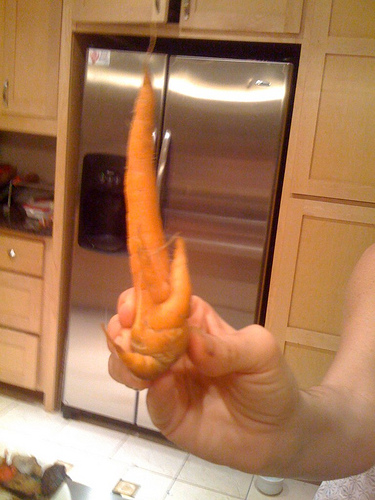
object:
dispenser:
[77, 151, 126, 256]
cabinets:
[0, 0, 64, 121]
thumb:
[186, 323, 281, 381]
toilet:
[51, 40, 296, 438]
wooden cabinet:
[328, 0, 374, 44]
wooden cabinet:
[309, 50, 375, 193]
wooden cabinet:
[287, 198, 375, 340]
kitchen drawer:
[0, 229, 45, 279]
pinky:
[101, 322, 169, 383]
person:
[103, 238, 375, 481]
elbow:
[316, 361, 375, 480]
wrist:
[267, 382, 335, 482]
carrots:
[101, 62, 193, 379]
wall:
[0, 0, 375, 487]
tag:
[86, 48, 111, 69]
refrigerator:
[56, 50, 298, 419]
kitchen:
[0, 0, 375, 499]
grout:
[0, 451, 78, 500]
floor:
[0, 387, 325, 499]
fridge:
[63, 34, 300, 466]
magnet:
[86, 46, 111, 66]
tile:
[0, 375, 320, 499]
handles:
[151, 128, 173, 208]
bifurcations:
[150, 232, 189, 322]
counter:
[0, 182, 57, 240]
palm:
[184, 357, 291, 469]